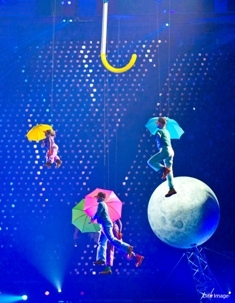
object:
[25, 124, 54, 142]
umbrella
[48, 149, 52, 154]
book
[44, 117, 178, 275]
some people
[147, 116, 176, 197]
man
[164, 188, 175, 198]
foot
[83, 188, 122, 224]
umbrella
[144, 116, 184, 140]
blue umbrella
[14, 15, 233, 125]
background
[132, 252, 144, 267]
boot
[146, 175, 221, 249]
moon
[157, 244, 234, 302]
tower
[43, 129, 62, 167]
girl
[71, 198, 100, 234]
umbrella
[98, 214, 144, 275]
people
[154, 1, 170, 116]
wires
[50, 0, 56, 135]
wires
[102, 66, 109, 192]
wires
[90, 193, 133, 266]
person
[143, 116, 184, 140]
umbrella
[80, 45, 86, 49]
dots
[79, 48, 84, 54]
dots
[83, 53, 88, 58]
dots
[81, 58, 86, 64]
dots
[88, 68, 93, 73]
dots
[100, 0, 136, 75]
handle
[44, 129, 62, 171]
people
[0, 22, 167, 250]
stripe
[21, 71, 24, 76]
dots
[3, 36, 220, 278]
panel